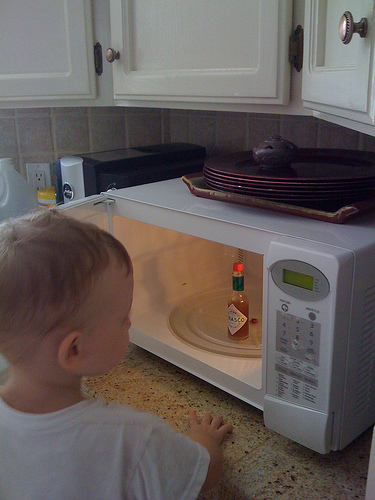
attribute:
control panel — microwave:
[261, 242, 336, 417]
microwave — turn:
[92, 149, 372, 458]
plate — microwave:
[164, 275, 265, 350]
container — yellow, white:
[26, 179, 68, 215]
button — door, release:
[259, 392, 335, 456]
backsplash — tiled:
[2, 107, 374, 214]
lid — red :
[231, 258, 244, 273]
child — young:
[1, 207, 236, 498]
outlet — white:
[22, 158, 56, 197]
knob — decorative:
[332, 7, 366, 47]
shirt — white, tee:
[0, 395, 210, 497]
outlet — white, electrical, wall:
[11, 140, 65, 209]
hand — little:
[182, 410, 232, 442]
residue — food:
[250, 315, 260, 329]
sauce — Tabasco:
[228, 301, 246, 334]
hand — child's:
[177, 404, 235, 451]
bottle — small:
[223, 259, 251, 344]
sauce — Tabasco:
[228, 298, 247, 338]